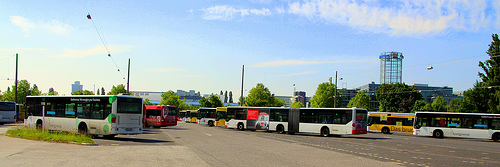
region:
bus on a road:
[18, 80, 150, 141]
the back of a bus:
[109, 95, 153, 139]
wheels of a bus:
[77, 120, 92, 135]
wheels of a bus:
[31, 116, 46, 130]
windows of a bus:
[29, 98, 111, 119]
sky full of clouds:
[205, 10, 445, 47]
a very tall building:
[370, 33, 425, 120]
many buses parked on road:
[177, 92, 494, 142]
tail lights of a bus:
[111, 110, 148, 127]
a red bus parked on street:
[143, 98, 188, 134]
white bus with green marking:
[21, 90, 146, 140]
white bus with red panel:
[223, 101, 295, 133]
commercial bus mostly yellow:
[369, 108, 422, 135]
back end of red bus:
[143, 100, 180, 132]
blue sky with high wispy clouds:
[180, 0, 487, 45]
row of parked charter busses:
[183, 103, 372, 141]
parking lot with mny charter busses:
[13, 88, 497, 145]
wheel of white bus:
[318, 124, 332, 137]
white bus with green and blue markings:
[19, 90, 147, 140]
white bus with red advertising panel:
[224, 103, 297, 134]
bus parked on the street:
[17, 87, 147, 141]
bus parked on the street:
[140, 100, 182, 132]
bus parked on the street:
[266, 100, 371, 140]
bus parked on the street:
[362, 104, 419, 138]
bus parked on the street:
[407, 104, 498, 143]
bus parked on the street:
[222, 102, 279, 132]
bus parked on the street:
[212, 105, 229, 130]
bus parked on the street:
[196, 102, 218, 131]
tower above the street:
[373, 46, 405, 88]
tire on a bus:
[317, 125, 331, 137]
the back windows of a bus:
[97, 95, 144, 116]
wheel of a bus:
[70, 113, 92, 136]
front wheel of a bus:
[27, 113, 52, 132]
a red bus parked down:
[148, 97, 180, 131]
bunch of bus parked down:
[176, 63, 495, 148]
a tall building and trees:
[371, 38, 420, 113]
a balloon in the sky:
[68, 7, 144, 79]